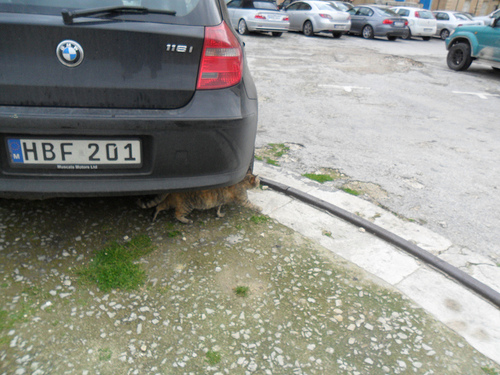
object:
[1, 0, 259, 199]
car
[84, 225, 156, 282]
grass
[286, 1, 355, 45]
car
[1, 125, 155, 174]
license plate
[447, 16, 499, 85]
car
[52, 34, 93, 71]
bmw logo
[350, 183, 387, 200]
pot holes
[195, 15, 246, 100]
brake light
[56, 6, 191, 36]
rear windshielf wipe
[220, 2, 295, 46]
vehicle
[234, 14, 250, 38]
tire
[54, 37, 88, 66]
logo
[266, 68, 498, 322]
parking lot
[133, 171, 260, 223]
cat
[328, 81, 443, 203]
street